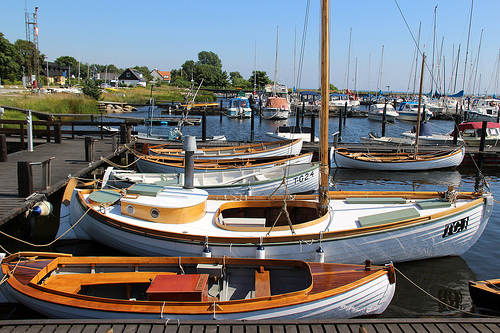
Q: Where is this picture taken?
A: A marina.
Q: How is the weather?
A: Sunny.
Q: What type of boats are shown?
A: Sail.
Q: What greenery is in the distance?
A: Trees.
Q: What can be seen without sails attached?
A: Masts.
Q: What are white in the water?
A: Boat hulls.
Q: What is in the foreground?
A: Pier.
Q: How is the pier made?
A: Of wood.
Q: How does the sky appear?
A: Blue.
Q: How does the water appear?
A: Calm.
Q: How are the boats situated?
A: Next to each other.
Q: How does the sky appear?
A: Blue and clear.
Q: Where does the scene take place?
A: At a boat dock.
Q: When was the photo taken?
A: During the daytime.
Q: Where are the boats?
A: On the water.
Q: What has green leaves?
A: The trees.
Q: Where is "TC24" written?
A: On white boat.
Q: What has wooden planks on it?
A: The decks.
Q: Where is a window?
A: On a house.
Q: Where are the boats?
A: River.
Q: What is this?
A: A lake scene.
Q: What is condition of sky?
A: Clear.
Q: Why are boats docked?
A: Ready to go out.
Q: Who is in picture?
A: No one.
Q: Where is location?
A: At a boat dock.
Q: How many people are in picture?
A: None.